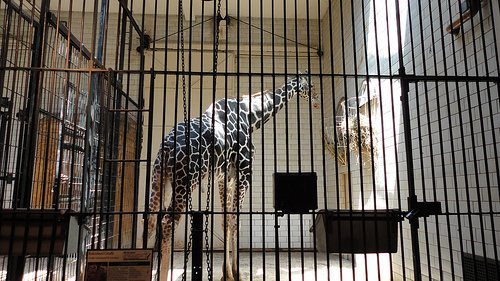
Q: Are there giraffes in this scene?
A: Yes, there is a giraffe.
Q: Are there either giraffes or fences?
A: Yes, there is a giraffe.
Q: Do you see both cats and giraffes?
A: No, there is a giraffe but no cats.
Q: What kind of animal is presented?
A: The animal is a giraffe.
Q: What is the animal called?
A: The animal is a giraffe.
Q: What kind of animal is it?
A: The animal is a giraffe.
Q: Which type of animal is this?
A: This is a giraffe.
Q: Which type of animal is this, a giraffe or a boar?
A: This is a giraffe.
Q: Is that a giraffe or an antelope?
A: That is a giraffe.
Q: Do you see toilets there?
A: No, there are no toilets.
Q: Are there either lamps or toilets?
A: No, there are no toilets or lamps.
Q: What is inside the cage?
A: The chain is inside the cage.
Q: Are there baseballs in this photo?
A: No, there are no baseballs.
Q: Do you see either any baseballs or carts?
A: No, there are no baseballs or carts.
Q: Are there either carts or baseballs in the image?
A: No, there are no baseballs or carts.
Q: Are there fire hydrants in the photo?
A: No, there are no fire hydrants.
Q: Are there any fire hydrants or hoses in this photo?
A: No, there are no fire hydrants or hoses.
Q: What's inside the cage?
A: The chain is inside the cage.